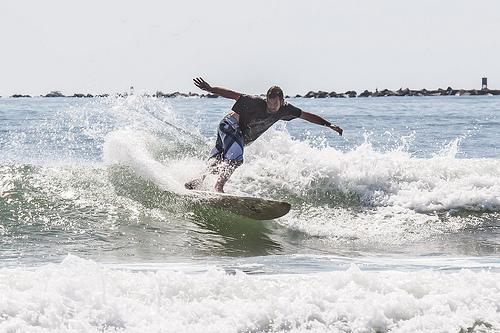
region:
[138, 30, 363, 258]
waves are in the water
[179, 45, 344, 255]
the man is wet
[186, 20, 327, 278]
the person is surfing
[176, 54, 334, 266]
the person is using a surfboard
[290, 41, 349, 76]
the sky is covered by clouds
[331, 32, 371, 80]
the clouds are grey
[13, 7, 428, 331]
it is sunny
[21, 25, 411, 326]
it is a daytime scene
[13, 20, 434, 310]
it is an outdoor scene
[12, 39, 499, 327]
it is in a waterbody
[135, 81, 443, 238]
this guy is surfing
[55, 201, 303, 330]
this is an ocean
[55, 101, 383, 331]
this is an outdoor photo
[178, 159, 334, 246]
this is a surf board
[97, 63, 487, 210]
i love this sporting activity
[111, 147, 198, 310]
this is a small wave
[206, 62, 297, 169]
the guy is dressed in black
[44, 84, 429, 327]
what a great picture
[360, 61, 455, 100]
this is vegetation in the background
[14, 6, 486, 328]
surfer at the ocean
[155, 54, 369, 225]
surfer riding the waves with his arms spread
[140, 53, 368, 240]
surer riding through high ocean waves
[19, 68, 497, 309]
white top-caps of ocean waves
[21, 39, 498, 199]
rocks in the backgrond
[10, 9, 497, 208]
partly cloudy sky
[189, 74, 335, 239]
surfer wearing patterned shorts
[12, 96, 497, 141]
still ocean in the background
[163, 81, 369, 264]
European male surer at the ocean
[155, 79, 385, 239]
surfer wearing a black shirt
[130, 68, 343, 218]
Man wearing shorts and shirt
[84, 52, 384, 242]
Man riding surfboard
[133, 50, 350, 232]
Man riding a wave on surfboard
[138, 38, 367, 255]
Man wearing blue shorts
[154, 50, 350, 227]
Man wearing dark blue shirt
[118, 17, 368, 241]
Man with brown hair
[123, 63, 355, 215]
Man riding surfboard on water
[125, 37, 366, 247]
Man holding arms out for balance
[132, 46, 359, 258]
Man riding a board on the water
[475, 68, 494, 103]
Small building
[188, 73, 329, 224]
a man on a surfboard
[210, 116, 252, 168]
a person wearing blue and black shorts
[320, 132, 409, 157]
the splash of an ocean wave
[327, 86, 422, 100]
a rocky shoreline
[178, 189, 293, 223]
a white surfboard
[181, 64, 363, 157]
a man with his arms out to the side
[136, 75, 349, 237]
a surfer riding a wave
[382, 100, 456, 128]
choppy ocean water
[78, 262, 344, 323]
a white water wave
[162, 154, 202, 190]
the wake of a surfboard